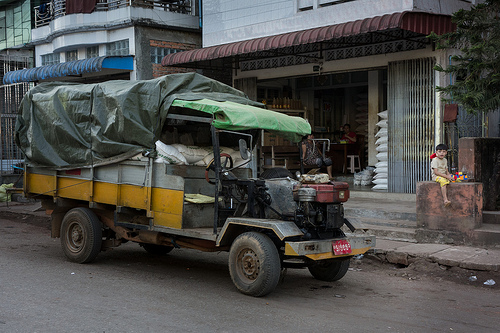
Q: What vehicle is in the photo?
A: A truck.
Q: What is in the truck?
A: White sacks.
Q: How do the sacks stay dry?
A: A tarp cover.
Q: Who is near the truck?
A: A little boy.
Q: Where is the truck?
A: In the road.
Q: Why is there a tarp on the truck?
A: It keep the sacks dry.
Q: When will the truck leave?
A: Truck leaves when the driver comes.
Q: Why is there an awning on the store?
A: To keep out the rain.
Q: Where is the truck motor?
A: In front of the truck.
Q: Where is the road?
A: In the city.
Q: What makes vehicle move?
A: Tires.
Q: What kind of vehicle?
A: Military.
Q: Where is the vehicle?
A: On the road.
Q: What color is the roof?
A: Green.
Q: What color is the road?
A: Black.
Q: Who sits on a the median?
A: A boy.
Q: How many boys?
A: One.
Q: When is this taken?
A: During the day.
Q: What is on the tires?
A: Dirt.